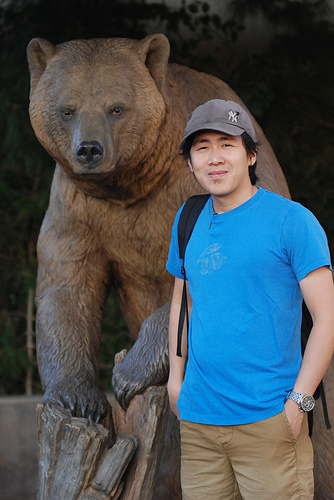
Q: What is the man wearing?
A: Blue shirt.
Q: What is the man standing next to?
A: A wooden bear.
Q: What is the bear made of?
A: Wood.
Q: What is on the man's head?
A: A cap.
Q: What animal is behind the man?
A: A bear.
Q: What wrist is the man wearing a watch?
A: Left.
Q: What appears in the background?
A: A bear.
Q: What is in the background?
A: A bear.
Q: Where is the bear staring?
A: Straight ahead.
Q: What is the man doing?
A: Posing for a picture.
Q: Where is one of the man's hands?
A: In his pocket.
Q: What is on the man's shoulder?
A: Backpack.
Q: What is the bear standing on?
A: A tree stump.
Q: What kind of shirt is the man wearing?
A: A short-sleeved t-shirt.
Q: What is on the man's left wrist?
A: A watch.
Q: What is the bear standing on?
A: A broken tree statue.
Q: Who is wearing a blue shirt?
A: The man.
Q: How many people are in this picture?
A: 1.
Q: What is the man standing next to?
A: A statue.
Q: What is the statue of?
A: A bear.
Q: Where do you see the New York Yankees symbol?
A: On his hat.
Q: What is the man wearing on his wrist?
A: A watch.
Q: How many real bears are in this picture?
A: 0.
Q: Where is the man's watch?
A: His left wrist.